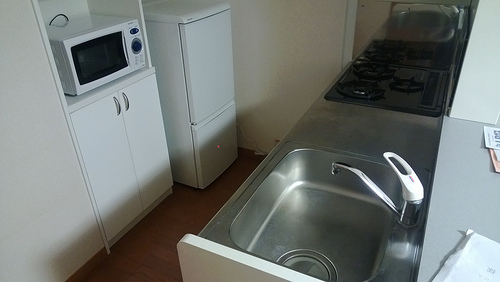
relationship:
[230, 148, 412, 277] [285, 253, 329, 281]
sink has hole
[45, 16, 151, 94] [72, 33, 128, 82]
microwave has door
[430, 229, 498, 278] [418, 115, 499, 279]
paper on counter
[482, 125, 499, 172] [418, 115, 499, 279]
paper on counter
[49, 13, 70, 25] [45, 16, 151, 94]
cord behind microwave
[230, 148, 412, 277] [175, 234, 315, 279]
sink has edge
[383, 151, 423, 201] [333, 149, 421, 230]
handle of faucet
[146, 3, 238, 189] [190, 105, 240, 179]
fridge has freezer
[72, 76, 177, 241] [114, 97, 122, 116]
cabinet has handle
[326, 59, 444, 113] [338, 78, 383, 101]
stove has grill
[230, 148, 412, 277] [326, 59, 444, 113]
sink by stove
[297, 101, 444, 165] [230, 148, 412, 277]
space near sink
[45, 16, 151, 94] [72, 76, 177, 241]
microwave above cabinet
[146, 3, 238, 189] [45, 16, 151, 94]
fridge beside microwave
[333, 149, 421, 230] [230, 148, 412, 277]
faucet on sink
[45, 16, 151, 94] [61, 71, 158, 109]
microwave on shelf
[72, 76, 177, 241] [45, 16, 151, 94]
cabinet under microwave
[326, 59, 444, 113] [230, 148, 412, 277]
stove near sink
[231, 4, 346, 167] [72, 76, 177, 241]
wall by cabinet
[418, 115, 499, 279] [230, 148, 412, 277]
counter above sink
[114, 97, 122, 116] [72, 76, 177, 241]
handle on cabinet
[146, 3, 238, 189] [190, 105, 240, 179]
fridge and freezer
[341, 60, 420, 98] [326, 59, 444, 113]
burners on stove